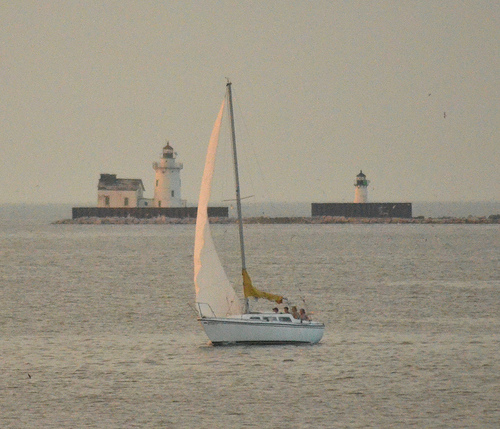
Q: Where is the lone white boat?
A: Sailing in the ocean.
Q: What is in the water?
A: A small white sailboat.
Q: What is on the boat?
A: A large white wind sail.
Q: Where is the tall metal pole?
A: On the boat.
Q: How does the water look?
A: Extremely calm.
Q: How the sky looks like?
A: Grey.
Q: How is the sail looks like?
A: Tall and white.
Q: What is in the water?
A: White sailboat.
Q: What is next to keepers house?
A: Lighthouse.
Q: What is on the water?
A: White boat.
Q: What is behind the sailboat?
A: Lighthouse.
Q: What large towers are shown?
A: Lighthouses.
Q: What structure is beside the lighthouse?
A: House.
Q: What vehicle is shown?
A: Boat.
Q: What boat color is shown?
A: White.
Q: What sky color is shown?
A: Grey.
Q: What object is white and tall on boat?
A: Sail.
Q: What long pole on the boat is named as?
A: Mast.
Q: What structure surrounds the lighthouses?
A: Fences.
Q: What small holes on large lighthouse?
A: Square windows.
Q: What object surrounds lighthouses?
A: Rocks.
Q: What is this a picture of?
A: A yacht.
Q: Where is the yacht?
A: In water.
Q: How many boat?
A: 1.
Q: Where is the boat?
A: In the water.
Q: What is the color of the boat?
A: White.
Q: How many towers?
A: 2.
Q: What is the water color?
A: Blue.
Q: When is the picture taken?
A: Daytime.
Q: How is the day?
A: Sunny.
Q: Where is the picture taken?
A: Outside, on the water.